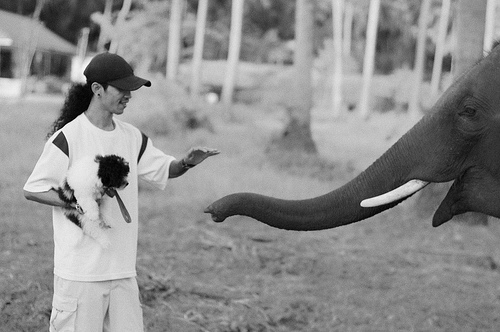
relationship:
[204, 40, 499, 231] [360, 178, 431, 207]
elephant has a horn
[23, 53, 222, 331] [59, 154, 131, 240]
female has a doll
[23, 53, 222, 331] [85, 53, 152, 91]
female has a hat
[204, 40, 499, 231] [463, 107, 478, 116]
elephant has a left eye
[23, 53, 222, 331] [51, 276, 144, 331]
female has on pants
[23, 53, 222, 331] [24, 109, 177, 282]
female has on a shirt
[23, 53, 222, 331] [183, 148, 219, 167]
female has a left hand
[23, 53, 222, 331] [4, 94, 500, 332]
female in a yard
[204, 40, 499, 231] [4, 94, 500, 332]
elephant in a yard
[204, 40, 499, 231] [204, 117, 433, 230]
elephant has a trunk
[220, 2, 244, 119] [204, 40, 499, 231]
tree behind elephant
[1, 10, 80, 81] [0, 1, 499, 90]
building in distance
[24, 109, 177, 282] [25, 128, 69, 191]
shirt has short sleeves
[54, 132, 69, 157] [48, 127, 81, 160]
stripe in on shoulder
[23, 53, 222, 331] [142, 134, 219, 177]
female has an arm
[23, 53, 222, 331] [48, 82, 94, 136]
female has hair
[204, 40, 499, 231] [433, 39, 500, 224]
elephant has a head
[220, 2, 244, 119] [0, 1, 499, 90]
tree in distance